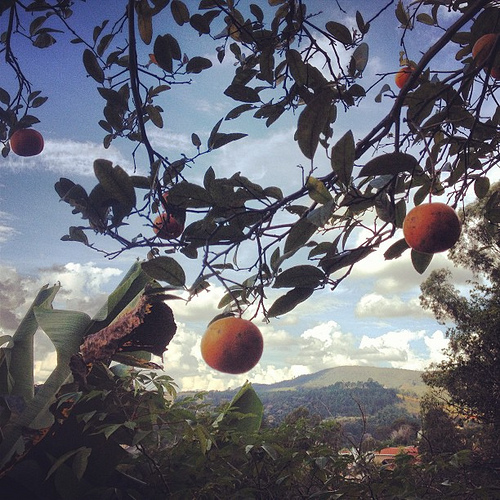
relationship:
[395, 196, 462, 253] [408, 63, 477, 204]
orange on branch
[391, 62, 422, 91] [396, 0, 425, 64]
orange on branch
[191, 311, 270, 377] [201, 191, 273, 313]
orange on branch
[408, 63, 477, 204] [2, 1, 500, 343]
branch of tree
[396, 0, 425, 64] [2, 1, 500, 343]
branch of tree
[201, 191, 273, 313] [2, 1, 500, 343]
branch of tree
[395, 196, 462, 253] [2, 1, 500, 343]
orange from tree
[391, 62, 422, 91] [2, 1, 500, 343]
orange from tree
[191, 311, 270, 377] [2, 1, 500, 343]
orange from tree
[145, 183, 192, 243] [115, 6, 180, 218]
oranges on branch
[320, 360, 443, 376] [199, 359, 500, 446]
top of mountain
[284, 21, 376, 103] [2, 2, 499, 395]
clouds in sky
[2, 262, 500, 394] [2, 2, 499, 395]
clouds in sky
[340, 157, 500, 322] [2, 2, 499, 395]
clouds in sky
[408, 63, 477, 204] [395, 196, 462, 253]
branch with orange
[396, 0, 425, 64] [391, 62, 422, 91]
branch with orange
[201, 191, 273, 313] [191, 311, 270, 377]
branch with orange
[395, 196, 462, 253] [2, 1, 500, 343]
orange in tree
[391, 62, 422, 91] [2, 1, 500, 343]
orange in tree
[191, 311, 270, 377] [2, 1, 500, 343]
orange in tree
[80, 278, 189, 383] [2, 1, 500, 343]
leaf on tree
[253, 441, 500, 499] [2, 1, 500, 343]
town below tree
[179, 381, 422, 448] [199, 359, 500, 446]
area on mountain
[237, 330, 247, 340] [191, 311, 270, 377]
spots on orange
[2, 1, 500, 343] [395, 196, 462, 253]
tree with orange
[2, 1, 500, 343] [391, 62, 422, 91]
tree with orange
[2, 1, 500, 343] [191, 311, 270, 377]
tree with orange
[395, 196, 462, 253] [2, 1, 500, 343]
orange on tree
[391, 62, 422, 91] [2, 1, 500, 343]
orange on tree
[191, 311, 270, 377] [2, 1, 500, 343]
orange on tree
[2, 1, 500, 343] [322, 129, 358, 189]
tree has leaves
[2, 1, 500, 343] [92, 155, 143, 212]
tree has leaves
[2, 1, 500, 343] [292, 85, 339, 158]
tree has leaves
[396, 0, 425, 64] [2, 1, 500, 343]
branch on tree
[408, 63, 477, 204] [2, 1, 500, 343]
branch on tree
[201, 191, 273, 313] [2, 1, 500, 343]
branch on tree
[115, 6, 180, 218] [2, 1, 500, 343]
branch on tree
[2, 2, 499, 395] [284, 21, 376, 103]
sky with clouds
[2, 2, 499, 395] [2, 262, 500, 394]
sky with clouds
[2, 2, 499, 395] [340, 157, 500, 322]
sky with clouds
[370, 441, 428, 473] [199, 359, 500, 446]
house at bottom of mountain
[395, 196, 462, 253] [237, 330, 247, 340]
orange has spots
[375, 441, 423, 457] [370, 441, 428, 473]
roof of house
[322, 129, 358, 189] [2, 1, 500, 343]
leaves on tree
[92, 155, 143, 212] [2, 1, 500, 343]
leaves on tree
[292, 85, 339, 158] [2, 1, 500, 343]
leaves on tree